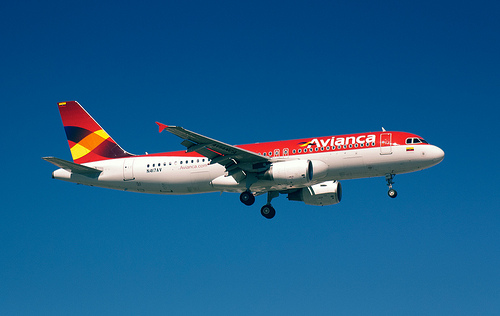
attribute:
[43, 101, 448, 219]
plane — flying, white, red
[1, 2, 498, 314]
sky — clear, blue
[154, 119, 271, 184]
wing — large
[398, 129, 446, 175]
head — streamlined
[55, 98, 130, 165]
tail — red, colorful, blue, yellow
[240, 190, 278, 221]
wheels — large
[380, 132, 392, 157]
door — closed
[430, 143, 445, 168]
nose — white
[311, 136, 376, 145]
lettering — white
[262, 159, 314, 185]
engine — large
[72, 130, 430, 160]
stripe — red